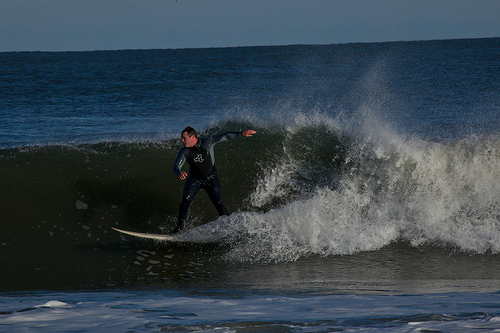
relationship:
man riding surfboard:
[169, 126, 260, 237] [106, 225, 175, 246]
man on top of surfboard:
[169, 126, 260, 237] [106, 225, 175, 246]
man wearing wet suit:
[169, 126, 260, 237] [172, 132, 244, 226]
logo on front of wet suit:
[189, 152, 207, 168] [172, 132, 244, 226]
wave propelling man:
[1, 112, 500, 271] [169, 126, 260, 237]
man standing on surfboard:
[169, 126, 260, 237] [106, 225, 175, 246]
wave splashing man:
[1, 112, 500, 271] [169, 126, 260, 237]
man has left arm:
[169, 126, 260, 237] [209, 125, 260, 144]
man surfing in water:
[169, 126, 260, 237] [1, 38, 500, 332]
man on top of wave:
[169, 126, 260, 237] [1, 112, 500, 271]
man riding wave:
[169, 126, 260, 237] [1, 112, 500, 271]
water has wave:
[1, 38, 500, 332] [1, 112, 500, 271]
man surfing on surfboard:
[169, 126, 260, 237] [106, 225, 175, 246]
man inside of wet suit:
[169, 126, 260, 237] [172, 132, 244, 226]